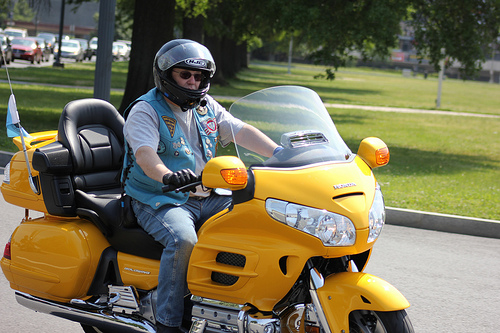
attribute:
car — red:
[11, 27, 48, 74]